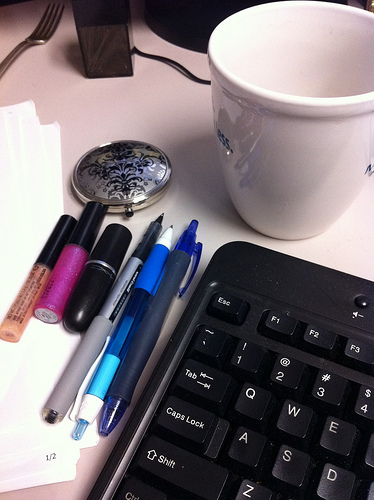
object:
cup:
[206, 0, 373, 240]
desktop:
[0, 0, 373, 500]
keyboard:
[85, 240, 373, 499]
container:
[30, 200, 109, 324]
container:
[1, 215, 75, 343]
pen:
[42, 210, 165, 424]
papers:
[1, 99, 87, 494]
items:
[96, 217, 203, 438]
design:
[77, 142, 167, 199]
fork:
[1, 0, 65, 83]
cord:
[134, 46, 211, 87]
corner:
[80, 241, 373, 500]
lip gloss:
[62, 222, 132, 334]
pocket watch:
[72, 139, 170, 219]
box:
[72, 0, 137, 79]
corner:
[0, 1, 66, 81]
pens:
[68, 221, 175, 442]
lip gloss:
[34, 199, 107, 325]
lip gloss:
[1, 212, 78, 343]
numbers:
[44, 452, 57, 466]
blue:
[215, 130, 232, 156]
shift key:
[130, 433, 229, 499]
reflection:
[209, 55, 268, 191]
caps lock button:
[150, 393, 231, 462]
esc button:
[206, 289, 249, 326]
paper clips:
[78, 21, 132, 80]